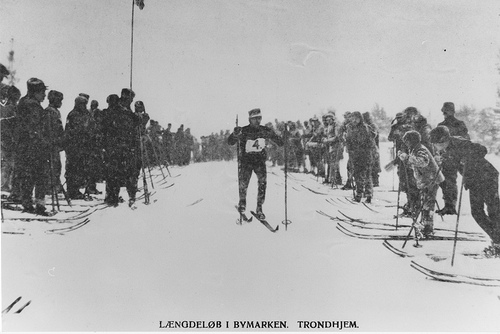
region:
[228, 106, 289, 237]
Short man skiing in snow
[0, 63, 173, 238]
Large group of people in snow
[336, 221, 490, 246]
Long black skis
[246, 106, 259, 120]
small furry hat on man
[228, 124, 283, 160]
Long sleeved black shirt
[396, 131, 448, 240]
Small person on skis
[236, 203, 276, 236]
Long black curved skis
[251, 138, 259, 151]
The number 4 on the skier's shirt.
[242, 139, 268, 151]
The sign on the skier's shirt.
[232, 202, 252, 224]
The left ski of the skier in the middle.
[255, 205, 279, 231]
The right ski of the skier in the middle.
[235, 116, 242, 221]
The left ski pole of the skier in the middle.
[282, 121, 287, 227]
The right ski pole of the skier in the middle.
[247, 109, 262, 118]
The hat the skier in the middle is wearing.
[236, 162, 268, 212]
The pants the skier in the middle is wearing.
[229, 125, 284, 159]
The jacket the skier in the middle is wearing.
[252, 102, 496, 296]
The people on the right watching the skier.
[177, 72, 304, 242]
a man on skis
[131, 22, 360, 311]
man is in a race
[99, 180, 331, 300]
snow on the ground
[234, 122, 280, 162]
man wearing a number sign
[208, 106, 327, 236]
man holding ski poles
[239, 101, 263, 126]
man wearing a hat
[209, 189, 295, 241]
a set of skis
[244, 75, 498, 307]
people standing on right side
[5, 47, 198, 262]
people standing on left side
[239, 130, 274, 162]
4 on the sign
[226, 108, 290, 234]
Skier on a slope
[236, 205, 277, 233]
Skis on the man's feet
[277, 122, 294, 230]
Ski pole in a man's hand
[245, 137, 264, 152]
White bib on a skier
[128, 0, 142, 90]
Flag on a flagpole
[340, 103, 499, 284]
Skiers lined up in the snow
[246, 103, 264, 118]
Hat on man's head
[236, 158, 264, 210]
Pants on man's legs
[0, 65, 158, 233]
Group of skiers standing together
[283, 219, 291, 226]
Ring around ski pole tip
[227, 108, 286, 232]
Skier on a slope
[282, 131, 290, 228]
Ski pole in man's hand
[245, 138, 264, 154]
White bib on skier's chest